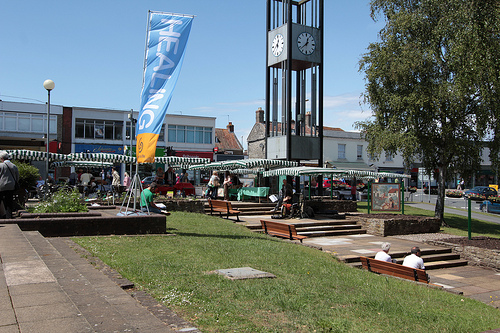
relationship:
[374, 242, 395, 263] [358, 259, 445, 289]
female sitting on bench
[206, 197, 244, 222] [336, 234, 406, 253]
bench beside concrete sidewalk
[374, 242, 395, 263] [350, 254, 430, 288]
female sitting on bench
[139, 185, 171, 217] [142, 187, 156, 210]
person in green shirt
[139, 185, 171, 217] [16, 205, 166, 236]
person sitting on stoop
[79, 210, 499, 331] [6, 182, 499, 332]
area in park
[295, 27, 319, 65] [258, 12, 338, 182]
clock in tower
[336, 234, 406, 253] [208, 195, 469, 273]
concrete sidewalk has steps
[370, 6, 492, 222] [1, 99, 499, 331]
tree in park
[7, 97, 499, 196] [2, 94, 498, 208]
buildings in park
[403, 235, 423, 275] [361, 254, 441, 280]
gentleman sitting on bench